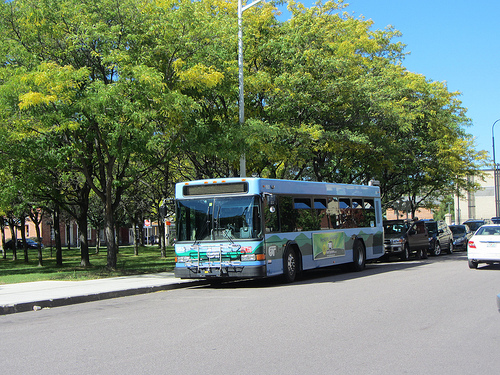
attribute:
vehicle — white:
[465, 223, 500, 271]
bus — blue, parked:
[176, 176, 388, 288]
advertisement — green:
[310, 229, 346, 260]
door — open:
[406, 216, 431, 252]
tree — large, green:
[7, 5, 263, 284]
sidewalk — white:
[2, 268, 209, 309]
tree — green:
[166, 8, 405, 188]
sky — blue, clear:
[272, 2, 499, 171]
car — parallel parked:
[385, 217, 430, 261]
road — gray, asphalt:
[4, 245, 499, 374]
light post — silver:
[239, 1, 260, 172]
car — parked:
[419, 219, 457, 254]